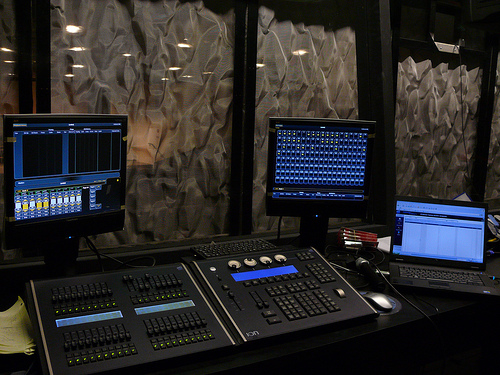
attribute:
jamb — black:
[233, 2, 256, 234]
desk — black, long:
[2, 209, 498, 372]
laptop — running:
[386, 193, 499, 310]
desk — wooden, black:
[383, 294, 418, 326]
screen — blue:
[253, 112, 391, 218]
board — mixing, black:
[21, 260, 235, 372]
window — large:
[386, 30, 486, 236]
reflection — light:
[178, 42, 190, 48]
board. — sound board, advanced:
[54, 229, 404, 371]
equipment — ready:
[14, 242, 391, 372]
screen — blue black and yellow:
[4, 108, 134, 246]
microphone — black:
[328, 236, 380, 286]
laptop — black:
[381, 179, 493, 301]